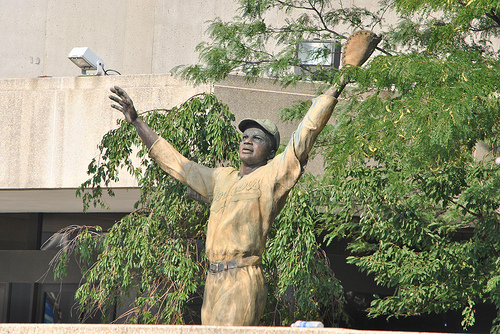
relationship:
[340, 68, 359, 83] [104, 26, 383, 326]
hand on portrait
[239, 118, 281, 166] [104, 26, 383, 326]
head on portrait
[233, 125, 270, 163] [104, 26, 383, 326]
face on portrait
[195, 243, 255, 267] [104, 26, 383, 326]
waist on portrait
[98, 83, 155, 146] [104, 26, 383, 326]
hand on portrait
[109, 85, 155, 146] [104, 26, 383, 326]
hand on portrait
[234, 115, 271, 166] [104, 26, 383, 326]
head on portrait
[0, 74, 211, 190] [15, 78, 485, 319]
wall on building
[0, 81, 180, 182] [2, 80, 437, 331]
wall on building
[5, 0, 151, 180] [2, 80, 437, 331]
wall on building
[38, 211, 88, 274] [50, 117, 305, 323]
needles on tree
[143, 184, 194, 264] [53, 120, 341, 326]
needles on tree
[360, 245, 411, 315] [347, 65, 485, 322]
needles on tree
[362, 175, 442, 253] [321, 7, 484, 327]
needles on tree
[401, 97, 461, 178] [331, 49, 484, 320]
needles on tree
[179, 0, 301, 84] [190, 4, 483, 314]
needles on tree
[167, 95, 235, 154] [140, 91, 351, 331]
needles on tree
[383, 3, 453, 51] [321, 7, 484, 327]
needles on tree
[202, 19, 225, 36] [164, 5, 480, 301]
needles on tree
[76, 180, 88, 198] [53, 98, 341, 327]
leaves on tree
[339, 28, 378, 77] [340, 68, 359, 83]
mitt on hand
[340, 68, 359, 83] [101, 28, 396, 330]
hand of player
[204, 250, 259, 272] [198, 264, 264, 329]
belt on pants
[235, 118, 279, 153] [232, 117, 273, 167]
cap on head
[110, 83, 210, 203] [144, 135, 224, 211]
arm in sleeve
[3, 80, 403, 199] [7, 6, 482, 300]
surface of building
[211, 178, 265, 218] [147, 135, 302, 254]
name on shirt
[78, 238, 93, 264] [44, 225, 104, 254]
leaves on branch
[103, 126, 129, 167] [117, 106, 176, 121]
leaves on branch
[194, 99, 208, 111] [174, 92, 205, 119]
leaves on branch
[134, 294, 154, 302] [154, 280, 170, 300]
leaves on branch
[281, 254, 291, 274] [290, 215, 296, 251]
leaves on branch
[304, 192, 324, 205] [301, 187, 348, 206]
leaves on branch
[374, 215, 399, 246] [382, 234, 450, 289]
leaves on branch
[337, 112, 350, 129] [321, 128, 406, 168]
leaves on branch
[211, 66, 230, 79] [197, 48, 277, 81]
leaves on branch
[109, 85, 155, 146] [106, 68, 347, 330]
hand of statue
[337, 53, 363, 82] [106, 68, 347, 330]
hand of statue